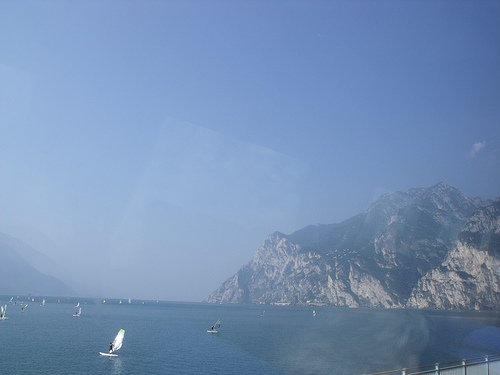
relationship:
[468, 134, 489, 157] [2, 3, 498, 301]
clouds in sky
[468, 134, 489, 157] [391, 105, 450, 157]
clouds are in sky